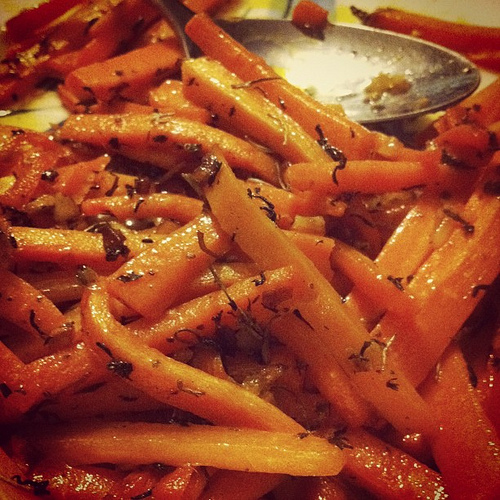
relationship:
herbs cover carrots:
[162, 143, 233, 191] [0, 0, 500, 500]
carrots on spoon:
[351, 69, 419, 102] [234, 18, 489, 124]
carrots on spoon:
[363, 71, 411, 105] [234, 18, 489, 124]